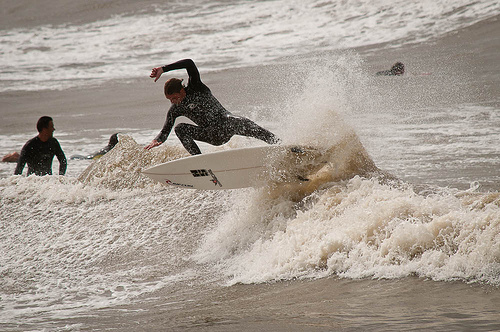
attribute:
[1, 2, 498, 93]
water — white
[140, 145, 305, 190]
surfboard — white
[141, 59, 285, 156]
surfer — falling, surfing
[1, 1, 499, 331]
water — grey, brown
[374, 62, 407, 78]
swimmer — swimming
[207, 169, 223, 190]
writing — red, black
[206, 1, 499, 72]
wave — starting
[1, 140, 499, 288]
wave — white water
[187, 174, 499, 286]
foam — white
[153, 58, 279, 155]
wetsuit — black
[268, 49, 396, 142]
water — white, flying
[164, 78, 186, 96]
hair — ponytail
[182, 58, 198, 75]
elbow — bent